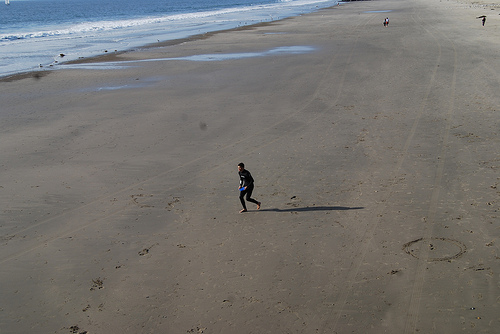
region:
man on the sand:
[193, 133, 291, 239]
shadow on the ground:
[293, 178, 375, 246]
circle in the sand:
[401, 218, 468, 283]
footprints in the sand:
[54, 200, 190, 330]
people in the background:
[354, 3, 421, 68]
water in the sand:
[190, 31, 330, 103]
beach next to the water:
[178, 28, 360, 156]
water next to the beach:
[38, 1, 128, 36]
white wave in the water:
[50, 6, 212, 56]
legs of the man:
[223, 193, 270, 225]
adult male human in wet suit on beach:
[226, 148, 271, 220]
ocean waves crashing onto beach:
[0, 2, 405, 88]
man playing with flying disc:
[217, 159, 274, 221]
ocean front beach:
[9, 9, 490, 324]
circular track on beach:
[390, 227, 480, 267]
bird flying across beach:
[456, 7, 491, 48]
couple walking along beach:
[376, 15, 400, 35]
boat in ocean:
[2, 0, 20, 9]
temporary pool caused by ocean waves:
[6, 26, 319, 75]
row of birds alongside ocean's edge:
[10, 8, 290, 88]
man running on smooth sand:
[222, 137, 264, 216]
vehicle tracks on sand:
[344, 42, 494, 332]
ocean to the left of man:
[11, 7, 274, 56]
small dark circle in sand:
[396, 226, 499, 288]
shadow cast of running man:
[259, 186, 384, 223]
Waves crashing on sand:
[51, 16, 188, 48]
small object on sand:
[372, 9, 424, 62]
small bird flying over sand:
[471, 3, 499, 34]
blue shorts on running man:
[232, 190, 247, 205]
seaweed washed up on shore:
[79, 254, 105, 289]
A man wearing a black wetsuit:
[206, 156, 303, 223]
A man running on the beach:
[206, 141, 290, 220]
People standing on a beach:
[371, 13, 400, 33]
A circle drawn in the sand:
[398, 224, 473, 268]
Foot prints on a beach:
[66, 264, 107, 332]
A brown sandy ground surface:
[23, 112, 180, 279]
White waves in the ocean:
[23, 11, 163, 42]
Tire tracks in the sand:
[317, 104, 453, 333]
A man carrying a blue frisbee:
[220, 150, 265, 216]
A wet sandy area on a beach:
[167, 41, 328, 75]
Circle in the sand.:
[401, 228, 470, 268]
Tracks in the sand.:
[72, 239, 153, 332]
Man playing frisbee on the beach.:
[232, 156, 262, 217]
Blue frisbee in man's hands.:
[237, 184, 249, 193]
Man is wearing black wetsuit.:
[232, 161, 261, 214]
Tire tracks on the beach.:
[321, 0, 468, 329]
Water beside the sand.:
[0, 0, 352, 81]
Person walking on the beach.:
[475, 13, 491, 27]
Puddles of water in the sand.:
[122, 41, 327, 61]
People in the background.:
[380, 13, 390, 26]